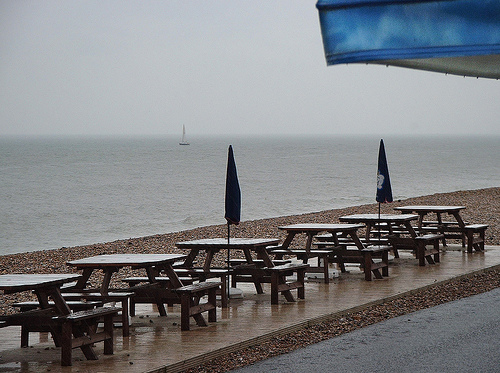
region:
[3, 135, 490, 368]
Multiple picnic tables by the beach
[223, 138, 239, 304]
A closed beach umbrella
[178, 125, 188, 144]
A sailboat in the water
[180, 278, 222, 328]
A bench behind a table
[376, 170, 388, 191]
A white logo on a beach umbrella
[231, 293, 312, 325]
A wet portion of lumber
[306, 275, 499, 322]
Gravel between two platforms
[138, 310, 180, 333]
Pinecones underneath a table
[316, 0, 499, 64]
The border of a blue overhang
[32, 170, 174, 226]
Ripples in the water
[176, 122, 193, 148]
a sailboat on the water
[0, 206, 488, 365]
a row of empty tables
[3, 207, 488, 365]
row of tables with wet top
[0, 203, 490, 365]
empty tables in the rain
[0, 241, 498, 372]
wet surface under the tables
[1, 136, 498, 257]
large body of water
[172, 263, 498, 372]
aggregate on the side of the raised area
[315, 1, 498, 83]
part of a fabric canopy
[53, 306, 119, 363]
a bench by a table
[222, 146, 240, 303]
fabric on a pole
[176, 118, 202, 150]
sailboat on the water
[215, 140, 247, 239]
closed picnic umbrella by water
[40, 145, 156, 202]
ocean water very calm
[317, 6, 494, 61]
blue porch roof over water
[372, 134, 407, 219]
blue umbrella with white logo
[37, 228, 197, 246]
gravel along the water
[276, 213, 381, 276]
wooden picnic table by water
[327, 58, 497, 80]
water droplets on roof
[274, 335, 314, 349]
gravel along the road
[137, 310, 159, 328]
leaves under the table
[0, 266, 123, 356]
table by the beach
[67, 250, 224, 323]
table by the beach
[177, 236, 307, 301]
table by the beach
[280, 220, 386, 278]
table by the beach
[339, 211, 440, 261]
table by the beach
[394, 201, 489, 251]
table by the beach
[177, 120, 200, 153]
boat on the water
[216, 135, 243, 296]
umbrella on the table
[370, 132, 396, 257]
umbrella on the table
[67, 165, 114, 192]
water by the tables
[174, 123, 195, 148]
a boat in the ocean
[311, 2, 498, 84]
a blue and white canopy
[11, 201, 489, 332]
a row of tables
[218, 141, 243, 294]
a closed umbrella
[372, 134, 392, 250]
a blue and white closed umbrella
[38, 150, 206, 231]
the rough ocean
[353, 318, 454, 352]
rain hitting the street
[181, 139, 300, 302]
patio furniture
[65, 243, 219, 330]
a wooden picnic table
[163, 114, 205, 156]
a boat in the rain